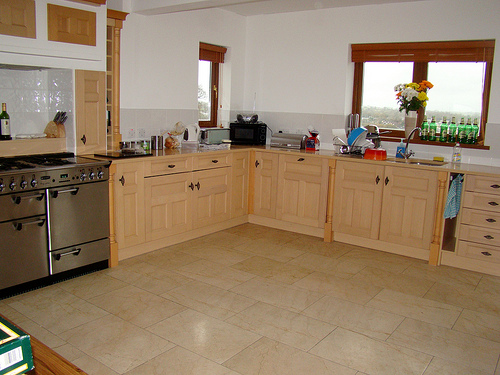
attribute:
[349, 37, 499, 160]
window — brown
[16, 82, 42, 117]
tiles — white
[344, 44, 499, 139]
window — large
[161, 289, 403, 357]
floor — clean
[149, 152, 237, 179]
drawers — brown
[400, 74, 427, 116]
flowers — white, yellow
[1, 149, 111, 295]
cooker — silvery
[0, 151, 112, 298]
oven — stainless steel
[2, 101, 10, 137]
bottle —  white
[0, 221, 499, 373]
floor — clean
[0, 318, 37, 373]
box — green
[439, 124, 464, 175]
bottle — plastic 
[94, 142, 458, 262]
wooden cupboards — brown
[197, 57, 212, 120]
window — smaller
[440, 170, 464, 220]
towel — blue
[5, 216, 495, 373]
floor tile — tan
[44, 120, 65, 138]
block — wooden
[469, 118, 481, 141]
bottle — green